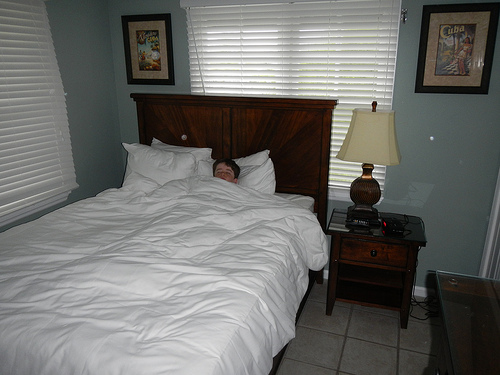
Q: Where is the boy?
A: In the bed.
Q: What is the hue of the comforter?
A: White.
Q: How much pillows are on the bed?
A: Three.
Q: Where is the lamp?
A: Nightstand.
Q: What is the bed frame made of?
A: Wood.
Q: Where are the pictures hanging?
A: Wall.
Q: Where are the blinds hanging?
A: Windows.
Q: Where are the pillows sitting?
A: Bed.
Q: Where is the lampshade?
A: Lamp.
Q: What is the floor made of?
A: Tiles.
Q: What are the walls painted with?
A: Blue paint.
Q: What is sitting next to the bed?
A: Nightstand.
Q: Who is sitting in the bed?
A: Boy.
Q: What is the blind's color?
A: White.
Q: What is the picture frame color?
A: Black.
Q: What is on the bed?
A: Fluffy white comforter.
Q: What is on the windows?
A: Shades.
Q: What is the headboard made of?
A: Wood.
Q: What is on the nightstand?
A: Lamp.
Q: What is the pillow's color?
A: White.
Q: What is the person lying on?
A: A bed.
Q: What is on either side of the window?
A: Framed pictures.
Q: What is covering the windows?
A: Blinds.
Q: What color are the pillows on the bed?
A: White.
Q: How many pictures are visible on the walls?
A: Two.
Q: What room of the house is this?
A: Bedroom.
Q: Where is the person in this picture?
A: In bed.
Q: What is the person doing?
A: Sleeping.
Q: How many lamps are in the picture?
A: One.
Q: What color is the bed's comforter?
A: White.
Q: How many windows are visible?
A: Two.